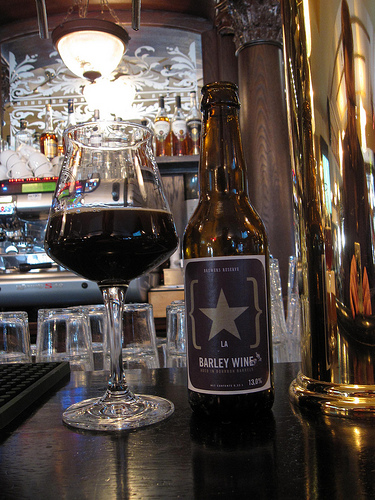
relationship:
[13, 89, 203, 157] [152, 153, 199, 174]
bottles sitting shelf